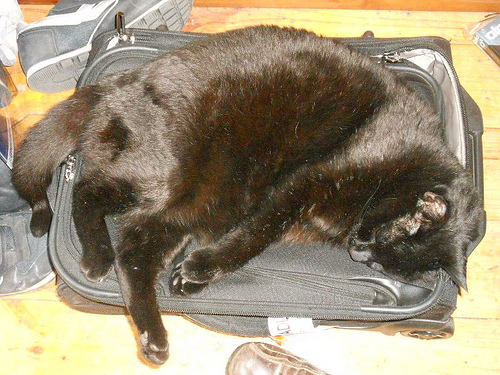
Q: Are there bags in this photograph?
A: Yes, there is a bag.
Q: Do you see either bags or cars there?
A: Yes, there is a bag.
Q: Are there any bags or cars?
A: Yes, there is a bag.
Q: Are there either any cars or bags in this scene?
A: Yes, there is a bag.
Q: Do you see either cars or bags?
A: Yes, there is a bag.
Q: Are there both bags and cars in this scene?
A: No, there is a bag but no cars.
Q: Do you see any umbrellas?
A: No, there are no umbrellas.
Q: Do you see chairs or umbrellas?
A: No, there are no umbrellas or chairs.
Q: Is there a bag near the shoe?
A: Yes, there is a bag near the shoe.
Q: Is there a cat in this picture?
A: Yes, there is a cat.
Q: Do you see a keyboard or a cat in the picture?
A: Yes, there is a cat.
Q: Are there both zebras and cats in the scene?
A: No, there is a cat but no zebras.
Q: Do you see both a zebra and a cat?
A: No, there is a cat but no zebras.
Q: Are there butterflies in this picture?
A: No, there are no butterflies.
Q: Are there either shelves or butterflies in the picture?
A: No, there are no butterflies or shelves.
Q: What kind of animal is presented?
A: The animal is a cat.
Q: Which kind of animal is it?
A: The animal is a cat.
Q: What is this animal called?
A: That is a cat.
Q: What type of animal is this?
A: That is a cat.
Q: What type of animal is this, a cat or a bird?
A: That is a cat.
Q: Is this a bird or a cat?
A: This is a cat.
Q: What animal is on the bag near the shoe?
A: The cat is on the bag.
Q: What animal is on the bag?
A: The cat is on the bag.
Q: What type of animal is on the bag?
A: The animal is a cat.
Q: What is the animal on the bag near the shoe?
A: The animal is a cat.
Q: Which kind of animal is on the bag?
A: The animal is a cat.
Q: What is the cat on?
A: The cat is on the bag.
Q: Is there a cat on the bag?
A: Yes, there is a cat on the bag.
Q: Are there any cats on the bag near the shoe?
A: Yes, there is a cat on the bag.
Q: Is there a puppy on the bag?
A: No, there is a cat on the bag.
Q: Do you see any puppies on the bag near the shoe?
A: No, there is a cat on the bag.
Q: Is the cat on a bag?
A: Yes, the cat is on a bag.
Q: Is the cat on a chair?
A: No, the cat is on a bag.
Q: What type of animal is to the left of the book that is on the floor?
A: The animal is a cat.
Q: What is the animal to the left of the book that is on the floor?
A: The animal is a cat.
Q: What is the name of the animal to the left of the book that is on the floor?
A: The animal is a cat.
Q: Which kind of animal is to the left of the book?
A: The animal is a cat.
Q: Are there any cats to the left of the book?
A: Yes, there is a cat to the left of the book.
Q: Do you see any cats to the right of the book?
A: No, the cat is to the left of the book.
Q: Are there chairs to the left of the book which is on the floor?
A: No, there is a cat to the left of the book.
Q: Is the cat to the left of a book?
A: Yes, the cat is to the left of a book.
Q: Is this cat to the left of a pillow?
A: No, the cat is to the left of a book.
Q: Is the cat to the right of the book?
A: No, the cat is to the left of the book.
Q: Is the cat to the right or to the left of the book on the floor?
A: The cat is to the left of the book.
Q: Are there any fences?
A: No, there are no fences.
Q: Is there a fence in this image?
A: No, there are no fences.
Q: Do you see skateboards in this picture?
A: No, there are no skateboards.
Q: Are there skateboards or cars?
A: No, there are no skateboards or cars.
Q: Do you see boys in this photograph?
A: No, there are no boys.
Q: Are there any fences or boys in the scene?
A: No, there are no boys or fences.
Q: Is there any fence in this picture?
A: No, there are no fences.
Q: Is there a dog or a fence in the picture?
A: No, there are no fences or dogs.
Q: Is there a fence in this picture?
A: No, there are no fences.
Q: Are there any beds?
A: No, there are no beds.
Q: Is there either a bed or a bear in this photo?
A: No, there are no beds or bears.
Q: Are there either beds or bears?
A: No, there are no beds or bears.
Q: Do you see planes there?
A: No, there are no planes.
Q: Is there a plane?
A: No, there are no airplanes.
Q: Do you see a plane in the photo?
A: No, there are no airplanes.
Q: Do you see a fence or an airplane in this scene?
A: No, there are no airplanes or fences.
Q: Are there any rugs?
A: No, there are no rugs.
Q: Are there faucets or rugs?
A: No, there are no rugs or faucets.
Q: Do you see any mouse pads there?
A: No, there are no mouse pads.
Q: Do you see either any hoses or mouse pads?
A: No, there are no mouse pads or hoses.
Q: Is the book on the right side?
A: Yes, the book is on the right of the image.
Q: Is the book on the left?
A: No, the book is on the right of the image.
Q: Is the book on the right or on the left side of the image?
A: The book is on the right of the image.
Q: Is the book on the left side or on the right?
A: The book is on the right of the image.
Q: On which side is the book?
A: The book is on the right of the image.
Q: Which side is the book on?
A: The book is on the right of the image.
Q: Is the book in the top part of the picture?
A: Yes, the book is in the top of the image.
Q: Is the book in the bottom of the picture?
A: No, the book is in the top of the image.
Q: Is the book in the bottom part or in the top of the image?
A: The book is in the top of the image.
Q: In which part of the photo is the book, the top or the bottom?
A: The book is in the top of the image.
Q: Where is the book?
A: The book is on the floor.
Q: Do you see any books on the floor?
A: Yes, there is a book on the floor.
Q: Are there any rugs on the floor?
A: No, there is a book on the floor.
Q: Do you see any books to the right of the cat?
A: Yes, there is a book to the right of the cat.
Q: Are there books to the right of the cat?
A: Yes, there is a book to the right of the cat.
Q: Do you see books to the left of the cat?
A: No, the book is to the right of the cat.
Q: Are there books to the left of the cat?
A: No, the book is to the right of the cat.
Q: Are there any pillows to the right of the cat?
A: No, there is a book to the right of the cat.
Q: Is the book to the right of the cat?
A: Yes, the book is to the right of the cat.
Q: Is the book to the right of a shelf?
A: No, the book is to the right of the cat.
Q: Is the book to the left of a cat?
A: No, the book is to the right of a cat.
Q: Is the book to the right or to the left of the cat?
A: The book is to the right of the cat.